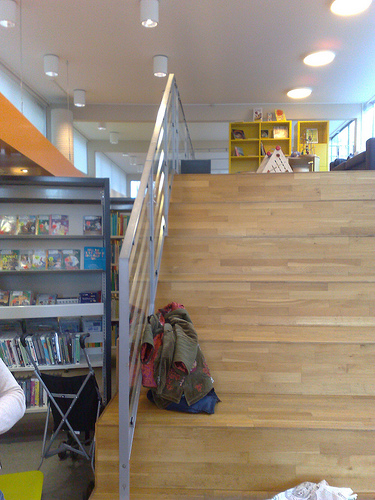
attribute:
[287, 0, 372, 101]
lights — round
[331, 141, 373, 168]
couch — brown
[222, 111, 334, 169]
shelf — yellow book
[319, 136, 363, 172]
couch — brown 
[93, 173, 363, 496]
stairs — wooden 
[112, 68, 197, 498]
balcony — white 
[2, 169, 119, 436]
shelf — large black book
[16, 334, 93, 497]
stroller — black 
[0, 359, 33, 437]
arm — person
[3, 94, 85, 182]
wall — orange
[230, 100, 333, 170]
cup board — object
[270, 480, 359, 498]
paper — part 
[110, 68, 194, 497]
stand — iron 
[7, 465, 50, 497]
floor — cloth 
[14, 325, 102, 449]
stroller — inside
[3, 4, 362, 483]
building — side of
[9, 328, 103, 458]
stroller — black